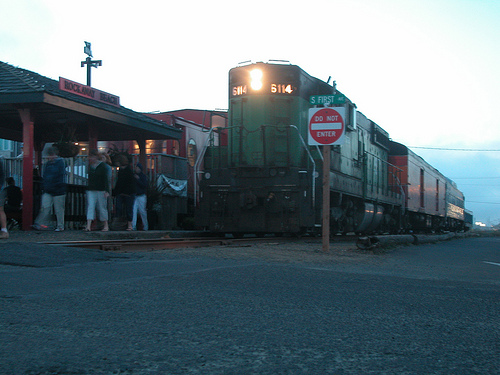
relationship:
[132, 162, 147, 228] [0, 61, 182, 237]
person in station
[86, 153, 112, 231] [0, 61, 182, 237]
person in station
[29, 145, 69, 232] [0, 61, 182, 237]
people in station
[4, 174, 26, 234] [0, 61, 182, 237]
person in station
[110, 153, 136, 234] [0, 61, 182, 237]
person in station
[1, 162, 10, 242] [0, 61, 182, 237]
person in station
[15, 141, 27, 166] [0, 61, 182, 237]
person in station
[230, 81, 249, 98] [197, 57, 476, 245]
number on train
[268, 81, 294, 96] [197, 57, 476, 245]
number on train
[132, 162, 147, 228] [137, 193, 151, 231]
person has leg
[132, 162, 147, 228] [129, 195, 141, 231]
person has leg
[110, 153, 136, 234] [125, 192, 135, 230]
person has leg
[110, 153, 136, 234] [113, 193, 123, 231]
person has leg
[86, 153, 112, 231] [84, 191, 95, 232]
person has a leg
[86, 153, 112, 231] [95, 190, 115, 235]
person has a leg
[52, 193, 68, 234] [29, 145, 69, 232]
leg of a people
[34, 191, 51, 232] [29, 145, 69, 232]
leg of a people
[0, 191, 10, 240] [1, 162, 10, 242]
leg of person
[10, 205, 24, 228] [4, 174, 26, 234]
leg of person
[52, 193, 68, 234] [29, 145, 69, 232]
leg of people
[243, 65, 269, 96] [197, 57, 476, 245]
light on train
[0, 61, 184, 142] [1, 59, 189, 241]
roof of house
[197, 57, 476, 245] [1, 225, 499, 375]
train on road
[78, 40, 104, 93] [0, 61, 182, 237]
wind vale on top of station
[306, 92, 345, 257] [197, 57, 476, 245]
street sign next to train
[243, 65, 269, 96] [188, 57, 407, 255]
light on car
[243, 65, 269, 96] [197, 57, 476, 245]
light on front of train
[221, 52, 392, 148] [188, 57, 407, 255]
top of car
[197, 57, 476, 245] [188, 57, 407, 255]
train has car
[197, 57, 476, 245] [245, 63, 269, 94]
train has lights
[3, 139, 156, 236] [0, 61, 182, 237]
people at station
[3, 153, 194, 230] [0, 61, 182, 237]
fence at station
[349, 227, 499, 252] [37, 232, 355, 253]
logs along tracks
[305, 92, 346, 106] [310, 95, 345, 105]
sign for s first st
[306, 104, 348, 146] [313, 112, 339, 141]
sign says do not enter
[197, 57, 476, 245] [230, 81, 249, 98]
train has number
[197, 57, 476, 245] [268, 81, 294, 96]
train has number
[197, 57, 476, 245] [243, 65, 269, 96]
train has light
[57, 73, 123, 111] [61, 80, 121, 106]
sign for rockaway beach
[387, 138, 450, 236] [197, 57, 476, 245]
car on train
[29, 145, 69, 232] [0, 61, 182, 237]
people at station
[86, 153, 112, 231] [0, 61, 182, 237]
person at station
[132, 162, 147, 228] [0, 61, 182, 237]
person at station